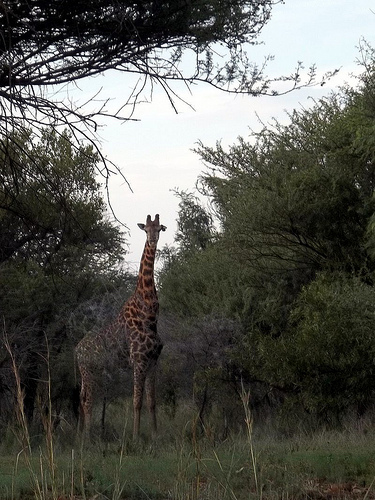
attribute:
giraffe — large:
[72, 214, 165, 455]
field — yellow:
[2, 403, 373, 500]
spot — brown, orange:
[143, 279, 153, 287]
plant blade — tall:
[233, 379, 263, 491]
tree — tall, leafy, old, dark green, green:
[298, 61, 374, 415]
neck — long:
[140, 244, 157, 289]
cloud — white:
[278, 65, 373, 101]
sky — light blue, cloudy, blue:
[3, 4, 374, 267]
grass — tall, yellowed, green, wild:
[183, 414, 244, 498]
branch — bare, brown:
[2, 56, 139, 229]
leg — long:
[132, 367, 146, 450]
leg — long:
[144, 369, 158, 442]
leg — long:
[79, 382, 92, 438]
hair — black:
[69, 387, 81, 412]